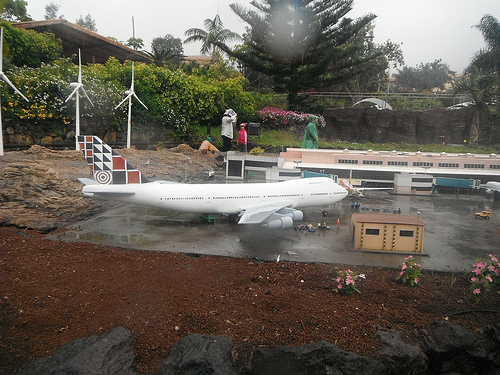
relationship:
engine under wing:
[260, 218, 300, 240] [221, 187, 274, 237]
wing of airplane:
[221, 187, 274, 237] [74, 134, 348, 229]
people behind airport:
[177, 107, 357, 162] [76, 148, 496, 235]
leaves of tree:
[224, 22, 298, 80] [231, 5, 407, 129]